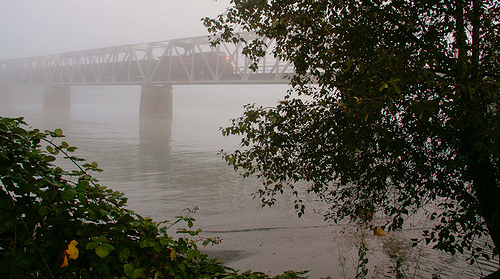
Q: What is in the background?
A: Bridge.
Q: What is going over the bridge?
A: Train.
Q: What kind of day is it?
A: Foggy.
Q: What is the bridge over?
A: River.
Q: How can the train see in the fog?
A: Light.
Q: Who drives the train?
A: Conductor.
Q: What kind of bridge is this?
A: Train.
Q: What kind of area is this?
A: Riverside.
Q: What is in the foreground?
A: Tree.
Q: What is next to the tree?
A: Leafy bushes.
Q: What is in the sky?
A: Fog.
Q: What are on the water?
A: Ripples.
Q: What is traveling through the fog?
A: The train.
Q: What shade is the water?
A: Gray.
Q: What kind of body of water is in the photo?
A: A river.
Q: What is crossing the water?
A: Bridge.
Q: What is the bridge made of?
A: Steel.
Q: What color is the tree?
A: Green.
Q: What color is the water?
A: Gray.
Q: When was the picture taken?
A: Daytime.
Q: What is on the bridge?
A: A train.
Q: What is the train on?
A: The bridge.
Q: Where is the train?
A: On the bridge.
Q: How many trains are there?
A: One.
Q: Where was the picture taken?
A: Near bridge.